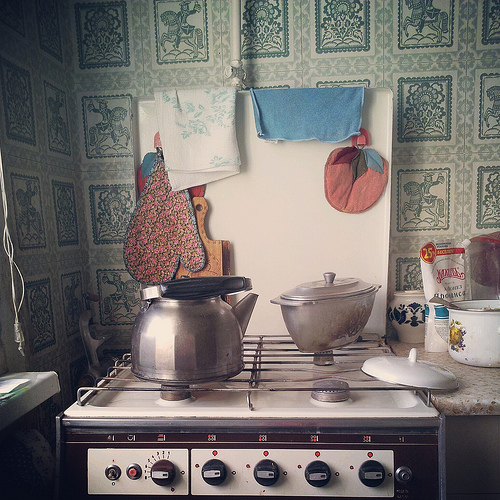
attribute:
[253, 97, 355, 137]
towel — blue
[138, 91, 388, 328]
board — white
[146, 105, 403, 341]
board — White 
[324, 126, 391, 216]
holder — pot holder, pumpkin designed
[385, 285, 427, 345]
tin — white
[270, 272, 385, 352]
container — silver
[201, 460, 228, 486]
knob — black 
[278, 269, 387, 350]
glassware — Distorted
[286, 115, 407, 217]
holder — circular, pot holder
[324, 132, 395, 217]
pot holder — pink 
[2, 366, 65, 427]
window sill — white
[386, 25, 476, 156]
wallpaper — white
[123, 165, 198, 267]
holder — hand shaped, pot holder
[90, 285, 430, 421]
burners — metal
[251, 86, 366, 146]
wash cloth — blue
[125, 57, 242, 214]
towel — white 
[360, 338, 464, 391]
top — white, metal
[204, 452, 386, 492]
knobs — black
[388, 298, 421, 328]
pattern — blue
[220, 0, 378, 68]
pattern — green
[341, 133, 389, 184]
designs — blue 